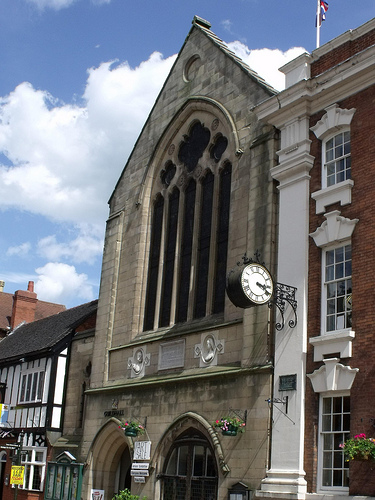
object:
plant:
[214, 415, 247, 435]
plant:
[117, 413, 144, 437]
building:
[0, 299, 99, 497]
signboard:
[9, 465, 24, 487]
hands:
[256, 282, 269, 297]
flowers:
[127, 419, 141, 427]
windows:
[39, 447, 80, 500]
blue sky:
[2, 0, 373, 106]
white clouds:
[1, 86, 38, 153]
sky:
[0, 1, 372, 314]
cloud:
[22, 260, 95, 307]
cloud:
[24, 104, 107, 198]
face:
[241, 262, 273, 304]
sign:
[278, 374, 297, 391]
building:
[260, 23, 375, 500]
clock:
[225, 262, 273, 310]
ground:
[173, 44, 190, 62]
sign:
[132, 439, 151, 461]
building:
[81, 13, 281, 497]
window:
[138, 96, 238, 333]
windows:
[18, 372, 46, 406]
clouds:
[98, 72, 144, 127]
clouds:
[235, 42, 302, 95]